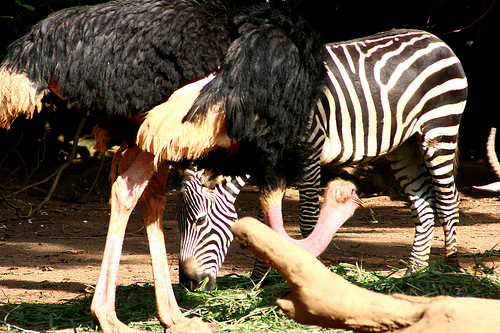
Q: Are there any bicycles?
A: No, there are no bicycles.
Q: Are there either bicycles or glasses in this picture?
A: No, there are no bicycles or glasses.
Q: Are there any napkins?
A: No, there are no napkins.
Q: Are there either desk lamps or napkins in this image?
A: No, there are no napkins or desk lamps.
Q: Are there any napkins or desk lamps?
A: No, there are no napkins or desk lamps.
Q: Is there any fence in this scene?
A: No, there are no fences.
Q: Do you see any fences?
A: No, there are no fences.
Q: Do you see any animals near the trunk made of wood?
A: Yes, there is an animal near the trunk.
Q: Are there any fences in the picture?
A: No, there are no fences.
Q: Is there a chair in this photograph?
A: No, there are no chairs.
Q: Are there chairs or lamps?
A: No, there are no chairs or lamps.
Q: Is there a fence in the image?
A: No, there are no fences.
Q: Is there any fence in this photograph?
A: No, there are no fences.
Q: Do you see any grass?
A: Yes, there is grass.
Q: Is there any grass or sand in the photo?
A: Yes, there is grass.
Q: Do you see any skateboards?
A: No, there are no skateboards.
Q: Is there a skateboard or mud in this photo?
A: No, there are no skateboards or mud.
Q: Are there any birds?
A: Yes, there is a bird.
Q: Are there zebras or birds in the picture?
A: Yes, there is a bird.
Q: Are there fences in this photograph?
A: No, there are no fences.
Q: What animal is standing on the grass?
A: The bird is standing on the grass.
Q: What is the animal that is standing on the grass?
A: The animal is a bird.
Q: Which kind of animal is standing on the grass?
A: The animal is a bird.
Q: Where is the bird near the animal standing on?
A: The bird is standing on the grass.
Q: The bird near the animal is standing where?
A: The bird is standing on the grass.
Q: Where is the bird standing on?
A: The bird is standing on the grass.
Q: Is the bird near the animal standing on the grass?
A: Yes, the bird is standing on the grass.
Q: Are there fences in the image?
A: No, there are no fences.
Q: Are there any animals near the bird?
A: Yes, there is an animal near the bird.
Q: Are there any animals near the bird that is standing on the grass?
A: Yes, there is an animal near the bird.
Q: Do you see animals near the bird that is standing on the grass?
A: Yes, there is an animal near the bird.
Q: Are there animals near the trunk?
A: Yes, there is an animal near the trunk.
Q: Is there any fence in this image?
A: No, there are no fences.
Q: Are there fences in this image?
A: No, there are no fences.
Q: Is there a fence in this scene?
A: No, there are no fences.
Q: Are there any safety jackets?
A: No, there are no safety jackets.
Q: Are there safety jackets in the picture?
A: No, there are no safety jackets.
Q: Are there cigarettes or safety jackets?
A: No, there are no safety jackets or cigarettes.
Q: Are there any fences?
A: No, there are no fences.